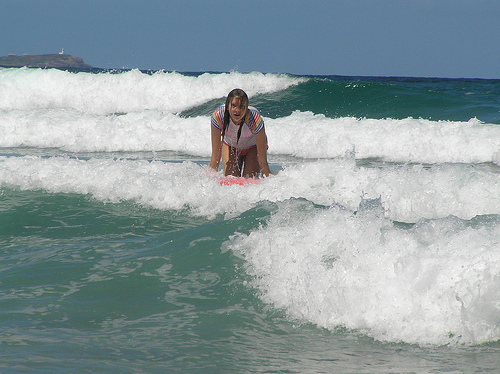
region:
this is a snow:
[262, 201, 499, 328]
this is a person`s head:
[214, 81, 254, 117]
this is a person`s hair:
[222, 84, 257, 147]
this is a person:
[207, 85, 287, 190]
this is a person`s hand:
[252, 119, 278, 177]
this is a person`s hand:
[204, 121, 222, 176]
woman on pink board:
[211, 81, 269, 196]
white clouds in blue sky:
[394, 19, 415, 44]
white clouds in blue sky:
[430, 21, 472, 69]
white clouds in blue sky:
[284, 15, 338, 55]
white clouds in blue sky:
[182, 33, 209, 50]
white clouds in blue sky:
[224, 15, 266, 60]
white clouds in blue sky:
[140, 8, 177, 58]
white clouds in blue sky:
[107, 15, 129, 39]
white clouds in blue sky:
[50, 13, 100, 54]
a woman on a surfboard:
[165, 69, 357, 212]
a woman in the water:
[179, 80, 368, 240]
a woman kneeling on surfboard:
[189, 67, 382, 298]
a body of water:
[37, 68, 417, 369]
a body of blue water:
[58, 94, 438, 352]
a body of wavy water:
[78, 66, 414, 347]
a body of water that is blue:
[79, 79, 481, 307]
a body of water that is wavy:
[82, 58, 494, 330]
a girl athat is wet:
[84, 48, 429, 355]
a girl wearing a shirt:
[185, 75, 300, 207]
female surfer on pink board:
[210, 71, 281, 209]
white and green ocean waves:
[310, 93, 365, 151]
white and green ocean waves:
[367, 269, 407, 301]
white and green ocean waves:
[417, 189, 471, 237]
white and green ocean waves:
[174, 271, 238, 331]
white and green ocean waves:
[245, 279, 316, 354]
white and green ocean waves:
[60, 226, 127, 281]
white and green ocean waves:
[92, 132, 154, 216]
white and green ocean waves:
[112, 95, 187, 172]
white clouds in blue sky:
[310, 11, 347, 62]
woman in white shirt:
[212, 103, 272, 149]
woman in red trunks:
[218, 143, 263, 168]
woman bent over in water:
[206, 84, 277, 188]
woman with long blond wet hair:
[221, 83, 256, 145]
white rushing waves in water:
[1, 65, 497, 327]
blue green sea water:
[6, 59, 499, 362]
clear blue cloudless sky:
[14, 5, 498, 75]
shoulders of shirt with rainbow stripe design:
[211, 105, 268, 129]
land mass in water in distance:
[1, 42, 102, 72]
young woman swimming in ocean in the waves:
[204, 85, 278, 189]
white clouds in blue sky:
[21, 6, 79, 47]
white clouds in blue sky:
[54, 16, 91, 77]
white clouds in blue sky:
[168, 18, 198, 42]